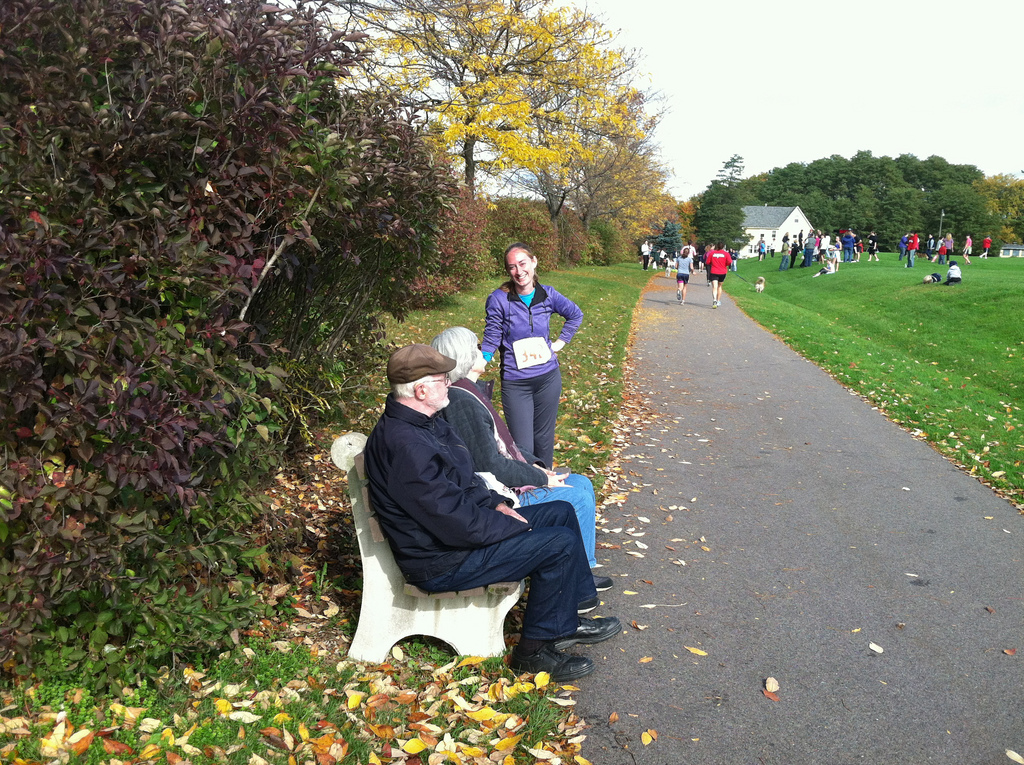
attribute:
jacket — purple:
[477, 281, 584, 377]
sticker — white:
[511, 328, 561, 372]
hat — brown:
[375, 335, 464, 381]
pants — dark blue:
[446, 491, 613, 667]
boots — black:
[489, 603, 632, 684]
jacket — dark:
[353, 400, 520, 584]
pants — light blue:
[520, 462, 609, 569]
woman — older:
[436, 322, 612, 565]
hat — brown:
[367, 336, 456, 410]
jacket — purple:
[516, 278, 596, 421]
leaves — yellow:
[590, 257, 662, 309]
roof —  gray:
[745, 203, 780, 216]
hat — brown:
[357, 336, 453, 425]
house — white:
[706, 177, 832, 275]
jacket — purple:
[493, 300, 582, 370]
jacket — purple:
[506, 295, 533, 347]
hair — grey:
[449, 323, 482, 376]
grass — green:
[749, 245, 1013, 423]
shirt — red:
[695, 242, 732, 281]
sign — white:
[505, 329, 564, 379]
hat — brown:
[386, 335, 447, 385]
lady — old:
[404, 314, 532, 442]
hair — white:
[436, 318, 491, 403]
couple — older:
[339, 307, 553, 509]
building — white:
[695, 190, 812, 279]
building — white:
[711, 186, 854, 284]